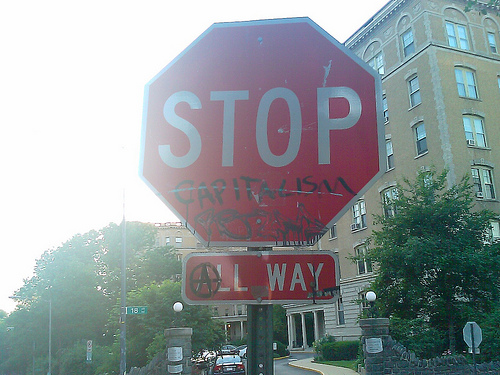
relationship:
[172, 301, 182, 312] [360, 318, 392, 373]
light on pillar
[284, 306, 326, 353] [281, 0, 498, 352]
columns in front of building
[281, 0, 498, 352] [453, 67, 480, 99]
building has window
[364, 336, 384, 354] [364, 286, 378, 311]
lsign under lamp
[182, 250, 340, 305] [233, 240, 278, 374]
sign on pole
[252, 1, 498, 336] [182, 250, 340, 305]
building behind sign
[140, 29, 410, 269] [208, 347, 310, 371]
sign across street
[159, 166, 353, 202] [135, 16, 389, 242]
capitalism written on sign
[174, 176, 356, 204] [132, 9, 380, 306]
capitalism written on sign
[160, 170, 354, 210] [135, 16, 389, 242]
black graffiti on sign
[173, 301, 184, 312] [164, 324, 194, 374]
light on top of post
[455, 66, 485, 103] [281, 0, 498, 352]
window in building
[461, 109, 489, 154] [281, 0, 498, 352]
window in building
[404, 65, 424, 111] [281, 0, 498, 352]
window in building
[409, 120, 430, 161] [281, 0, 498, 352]
window in building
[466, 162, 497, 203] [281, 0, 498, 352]
window in building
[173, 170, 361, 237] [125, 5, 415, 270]
spraypaint on sign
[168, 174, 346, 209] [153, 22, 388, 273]
graffiti on stop sign